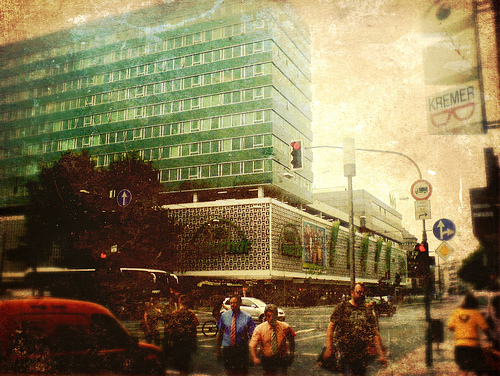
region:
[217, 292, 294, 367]
two men wearing ties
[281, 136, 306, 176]
traffic light glowing red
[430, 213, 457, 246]
blue sign with two arrows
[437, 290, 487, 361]
person in yellow shirt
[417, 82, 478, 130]
sign with red eyeglasses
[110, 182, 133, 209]
blue circular sign with arrow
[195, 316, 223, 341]
back tire of bicycle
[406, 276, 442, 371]
pole on city sidewalk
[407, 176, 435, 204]
sign with red circle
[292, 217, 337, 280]
sign on city building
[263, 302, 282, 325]
the head of a man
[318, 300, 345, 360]
the arm of a man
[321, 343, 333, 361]
the hand of a man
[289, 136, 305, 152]
a red stop light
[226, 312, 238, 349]
an orange neck tie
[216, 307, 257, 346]
a blue men's shirt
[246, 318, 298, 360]
an orange men's shirt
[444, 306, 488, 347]
a yellow women's shirt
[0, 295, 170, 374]
a red van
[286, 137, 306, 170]
a set of traffic lights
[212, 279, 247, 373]
man wearing blue shirt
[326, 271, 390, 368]
man wearing t-shirt and sunglasses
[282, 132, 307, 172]
Stop light on red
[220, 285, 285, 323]
white car traveling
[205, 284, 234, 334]
man riding bicycle in street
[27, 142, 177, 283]
tall tree in front of building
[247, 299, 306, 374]
man wearing orange shirt and tie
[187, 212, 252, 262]
name of store on building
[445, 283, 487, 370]
woman wearing yellow shirt and shorts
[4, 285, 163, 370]
red mini van stopped at light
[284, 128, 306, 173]
Traffic light in red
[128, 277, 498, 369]
People walking in the street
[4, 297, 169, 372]
Red minivan stopped in traffic lights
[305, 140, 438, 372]
Pole holding two traffic lights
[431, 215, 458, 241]
Round sign with white arrows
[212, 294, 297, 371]
Two men with ties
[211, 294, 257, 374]
Man wearing blue shirt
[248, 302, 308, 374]
Man wearing orange shirt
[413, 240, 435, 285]
Side traffic lights on pole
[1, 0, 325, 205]
Rectangular building of city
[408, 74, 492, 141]
A sign with red glasses on it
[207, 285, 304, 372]
Two men wearing ties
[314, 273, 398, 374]
A heavy man in a camo top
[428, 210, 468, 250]
A blue sign saying straight or right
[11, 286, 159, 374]
A red car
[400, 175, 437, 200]
A sign with a picture of a truck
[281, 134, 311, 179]
A red stop light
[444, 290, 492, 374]
The back of a man in a yellow shirt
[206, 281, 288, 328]
A white car behind some men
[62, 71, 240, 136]
The side of a building, with green walls